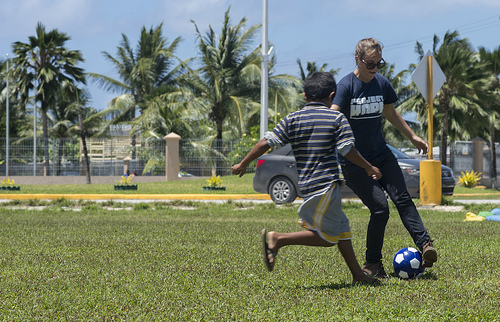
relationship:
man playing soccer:
[330, 29, 447, 290] [6, 0, 493, 318]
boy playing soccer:
[223, 66, 387, 311] [6, 0, 493, 318]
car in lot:
[245, 123, 460, 201] [12, 132, 497, 221]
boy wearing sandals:
[223, 66, 387, 311] [256, 226, 393, 304]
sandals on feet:
[256, 226, 393, 304] [254, 227, 388, 290]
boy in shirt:
[223, 66, 387, 311] [253, 103, 359, 200]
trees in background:
[3, 19, 495, 188] [1, 3, 498, 179]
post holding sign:
[413, 41, 453, 207] [406, 41, 453, 109]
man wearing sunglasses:
[330, 29, 447, 290] [357, 55, 389, 75]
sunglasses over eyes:
[357, 55, 389, 75] [360, 60, 381, 70]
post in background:
[413, 41, 453, 207] [1, 3, 498, 179]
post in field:
[413, 41, 453, 207] [4, 202, 500, 318]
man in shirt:
[330, 29, 447, 290] [326, 66, 406, 173]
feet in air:
[260, 229, 281, 270] [243, 214, 338, 280]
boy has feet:
[223, 66, 387, 311] [260, 229, 281, 270]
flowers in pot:
[454, 166, 484, 194] [454, 177, 479, 190]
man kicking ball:
[330, 37, 437, 278] [389, 238, 431, 282]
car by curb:
[245, 123, 460, 201] [1, 192, 499, 206]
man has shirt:
[330, 37, 437, 278] [326, 66, 406, 173]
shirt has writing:
[326, 66, 406, 173] [348, 92, 384, 122]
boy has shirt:
[223, 66, 387, 311] [253, 103, 359, 200]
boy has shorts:
[223, 66, 387, 311] [289, 182, 362, 243]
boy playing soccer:
[232, 71, 382, 286] [6, 0, 493, 318]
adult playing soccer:
[330, 29, 447, 290] [6, 0, 493, 318]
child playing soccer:
[223, 66, 387, 311] [6, 0, 493, 318]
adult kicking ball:
[330, 29, 447, 290] [389, 238, 431, 282]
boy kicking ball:
[232, 71, 382, 286] [389, 238, 431, 282]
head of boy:
[303, 65, 339, 114] [223, 66, 387, 311]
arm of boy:
[229, 110, 296, 184] [223, 66, 387, 311]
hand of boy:
[222, 156, 258, 177] [223, 66, 387, 311]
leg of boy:
[252, 197, 342, 278] [223, 66, 387, 311]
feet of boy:
[260, 229, 281, 270] [223, 66, 387, 311]